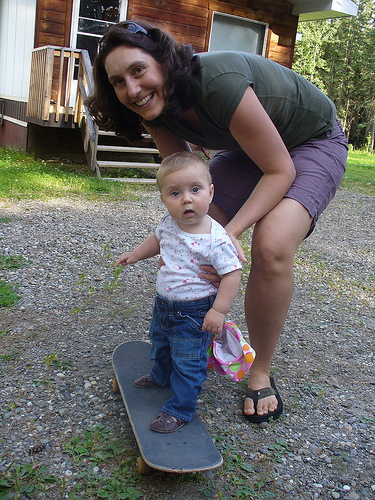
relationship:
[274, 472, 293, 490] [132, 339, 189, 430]
pebble by skateboard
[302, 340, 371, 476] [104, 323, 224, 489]
pebble by skateboard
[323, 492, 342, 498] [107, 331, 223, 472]
pebble by skateboard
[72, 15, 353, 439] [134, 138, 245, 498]
woman holding baby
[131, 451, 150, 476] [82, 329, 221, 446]
wheel of a skate board